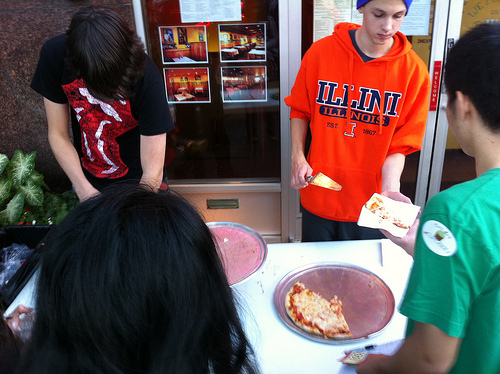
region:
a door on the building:
[298, 8, 478, 225]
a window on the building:
[141, 9, 277, 186]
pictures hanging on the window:
[160, 26, 261, 97]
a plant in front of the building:
[0, 158, 71, 238]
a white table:
[210, 244, 430, 370]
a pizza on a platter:
[282, 263, 381, 344]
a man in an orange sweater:
[294, 15, 422, 234]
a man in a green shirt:
[423, 29, 498, 355]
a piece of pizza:
[367, 189, 402, 221]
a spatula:
[302, 165, 346, 190]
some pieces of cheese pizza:
[288, 281, 348, 336]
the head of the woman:
[38, 191, 252, 372]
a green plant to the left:
[0, 148, 67, 221]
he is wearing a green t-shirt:
[403, 167, 498, 332]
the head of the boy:
[361, 1, 411, 41]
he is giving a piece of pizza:
[292, 1, 474, 253]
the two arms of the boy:
[42, 97, 165, 194]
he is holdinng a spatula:
[285, 123, 342, 193]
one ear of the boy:
[453, 92, 469, 122]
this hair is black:
[35, 193, 233, 365]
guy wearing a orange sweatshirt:
[296, 36, 417, 222]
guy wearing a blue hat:
[346, 0, 414, 14]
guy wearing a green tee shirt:
[386, 165, 499, 337]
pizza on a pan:
[281, 272, 356, 350]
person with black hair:
[37, 178, 234, 373]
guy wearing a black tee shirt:
[30, 39, 170, 194]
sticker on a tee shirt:
[421, 218, 466, 270]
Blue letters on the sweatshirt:
[293, 69, 415, 140]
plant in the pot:
[0, 143, 70, 230]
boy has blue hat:
[341, 0, 429, 6]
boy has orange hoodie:
[295, 32, 416, 204]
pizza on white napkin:
[351, 179, 411, 234]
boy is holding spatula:
[308, 150, 335, 196]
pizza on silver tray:
[297, 252, 396, 369]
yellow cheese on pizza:
[285, 273, 348, 327]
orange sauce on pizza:
[288, 292, 344, 322]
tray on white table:
[269, 268, 376, 370]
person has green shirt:
[439, 173, 499, 368]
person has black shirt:
[37, 39, 147, 191]